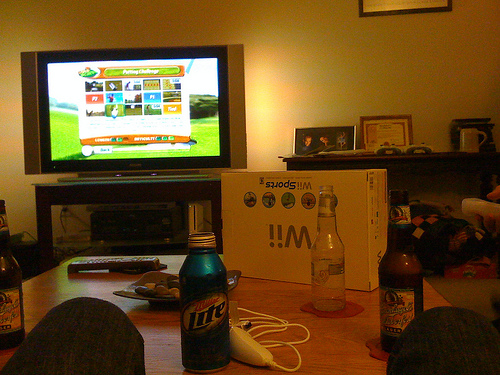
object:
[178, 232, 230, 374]
beer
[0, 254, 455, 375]
table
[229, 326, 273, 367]
wii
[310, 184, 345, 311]
glass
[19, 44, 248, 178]
tv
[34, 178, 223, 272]
table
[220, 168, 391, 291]
box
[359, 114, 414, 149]
frame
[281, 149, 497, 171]
table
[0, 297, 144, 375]
knee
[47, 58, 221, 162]
game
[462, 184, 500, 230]
controller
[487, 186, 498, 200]
hand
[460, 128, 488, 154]
mug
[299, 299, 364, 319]
coaster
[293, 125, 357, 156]
picture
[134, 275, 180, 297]
snacks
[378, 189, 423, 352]
bottle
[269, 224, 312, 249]
word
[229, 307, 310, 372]
controller